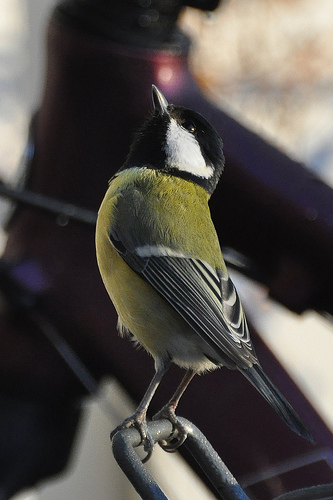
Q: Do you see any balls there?
A: No, there are no balls.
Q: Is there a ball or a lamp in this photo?
A: No, there are no balls or lamps.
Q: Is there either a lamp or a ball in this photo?
A: No, there are no balls or lamps.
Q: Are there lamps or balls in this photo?
A: No, there are no balls or lamps.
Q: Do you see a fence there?
A: No, there are no fences.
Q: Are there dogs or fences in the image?
A: No, there are no fences or dogs.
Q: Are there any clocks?
A: No, there are no clocks.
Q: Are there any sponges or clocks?
A: No, there are no clocks or sponges.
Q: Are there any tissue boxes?
A: No, there are no tissue boxes.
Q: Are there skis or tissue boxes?
A: No, there are no tissue boxes or skis.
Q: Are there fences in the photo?
A: No, there are no fences.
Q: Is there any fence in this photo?
A: No, there are no fences.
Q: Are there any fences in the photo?
A: No, there are no fences.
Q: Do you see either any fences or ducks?
A: No, there are no fences or ducks.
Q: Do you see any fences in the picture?
A: No, there are no fences.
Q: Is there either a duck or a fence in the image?
A: No, there are no fences or ducks.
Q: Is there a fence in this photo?
A: No, there are no fences.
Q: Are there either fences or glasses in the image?
A: No, there are no fences or glasses.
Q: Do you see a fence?
A: No, there are no fences.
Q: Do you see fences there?
A: No, there are no fences.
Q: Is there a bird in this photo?
A: Yes, there is a bird.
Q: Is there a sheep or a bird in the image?
A: Yes, there is a bird.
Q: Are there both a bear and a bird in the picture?
A: No, there is a bird but no bears.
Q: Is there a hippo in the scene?
A: No, there are no hippoes.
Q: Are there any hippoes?
A: No, there are no hippoes.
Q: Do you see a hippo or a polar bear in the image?
A: No, there are no hippoes or polar bears.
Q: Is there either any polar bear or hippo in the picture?
A: No, there are no hippoes or polar bears.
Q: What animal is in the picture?
A: The animal is a bird.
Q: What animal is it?
A: The animal is a bird.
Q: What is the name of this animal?
A: This is a bird.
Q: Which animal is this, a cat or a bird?
A: This is a bird.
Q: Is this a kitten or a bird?
A: This is a bird.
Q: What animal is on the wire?
A: The bird is on the wire.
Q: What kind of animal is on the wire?
A: The animal is a bird.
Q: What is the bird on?
A: The bird is on the wire.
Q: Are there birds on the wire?
A: Yes, there is a bird on the wire.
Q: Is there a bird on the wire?
A: Yes, there is a bird on the wire.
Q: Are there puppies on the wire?
A: No, there is a bird on the wire.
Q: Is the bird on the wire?
A: Yes, the bird is on the wire.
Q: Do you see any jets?
A: No, there are no jets.